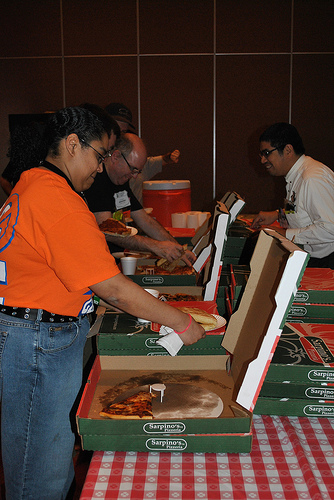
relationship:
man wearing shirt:
[242, 121, 332, 268] [280, 153, 333, 260]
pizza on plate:
[180, 306, 216, 331] [163, 312, 229, 337]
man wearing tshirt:
[85, 129, 201, 268] [87, 166, 145, 215]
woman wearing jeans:
[0, 102, 208, 500] [0, 314, 89, 499]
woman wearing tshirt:
[0, 102, 208, 500] [0, 168, 122, 320]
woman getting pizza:
[0, 102, 208, 500] [180, 306, 216, 331]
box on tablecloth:
[77, 423, 254, 455] [77, 415, 332, 499]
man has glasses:
[242, 121, 332, 268] [257, 144, 283, 159]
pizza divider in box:
[149, 380, 166, 402] [75, 224, 310, 436]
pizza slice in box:
[97, 386, 151, 420] [75, 224, 310, 436]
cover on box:
[218, 228, 310, 413] [75, 224, 310, 436]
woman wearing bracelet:
[0, 102, 208, 500] [174, 313, 194, 334]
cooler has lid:
[139, 177, 192, 229] [139, 177, 193, 191]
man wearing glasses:
[242, 121, 332, 268] [257, 144, 283, 159]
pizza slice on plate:
[95, 215, 133, 232] [102, 221, 139, 241]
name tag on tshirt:
[114, 190, 133, 211] [87, 166, 145, 215]